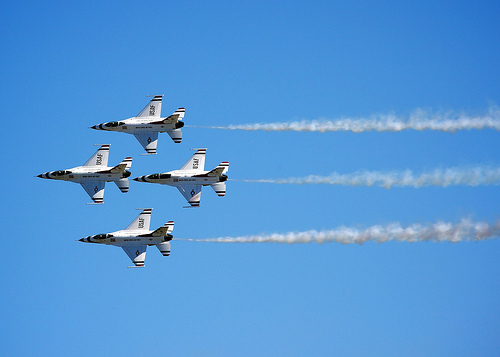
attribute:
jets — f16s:
[34, 94, 229, 272]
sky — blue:
[1, 2, 500, 357]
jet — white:
[34, 144, 132, 205]